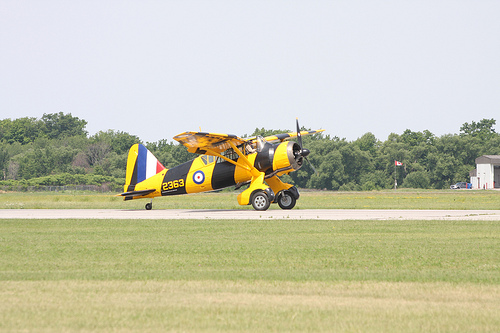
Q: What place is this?
A: It is an airport.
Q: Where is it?
A: This is at the airport.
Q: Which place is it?
A: It is an airport.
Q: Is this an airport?
A: Yes, it is an airport.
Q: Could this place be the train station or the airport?
A: It is the airport.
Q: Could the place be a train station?
A: No, it is an airport.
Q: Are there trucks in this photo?
A: No, there are no trucks.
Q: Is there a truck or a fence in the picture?
A: No, there are no trucks or fences.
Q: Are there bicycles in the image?
A: No, there are no bicycles.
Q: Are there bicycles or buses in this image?
A: No, there are no bicycles or buses.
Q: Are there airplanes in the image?
A: Yes, there is an airplane.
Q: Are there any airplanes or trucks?
A: Yes, there is an airplane.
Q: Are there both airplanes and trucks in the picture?
A: No, there is an airplane but no trucks.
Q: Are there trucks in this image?
A: No, there are no trucks.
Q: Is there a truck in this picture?
A: No, there are no trucks.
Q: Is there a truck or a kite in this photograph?
A: No, there are no trucks or kites.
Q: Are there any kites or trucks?
A: No, there are no trucks or kites.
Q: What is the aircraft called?
A: The aircraft is an airplane.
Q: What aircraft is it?
A: The aircraft is an airplane.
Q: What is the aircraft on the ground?
A: The aircraft is an airplane.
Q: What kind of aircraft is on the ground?
A: The aircraft is an airplane.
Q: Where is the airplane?
A: The airplane is on the ground.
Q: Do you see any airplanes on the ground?
A: Yes, there is an airplane on the ground.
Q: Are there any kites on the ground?
A: No, there is an airplane on the ground.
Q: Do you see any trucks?
A: No, there are no trucks.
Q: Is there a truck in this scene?
A: No, there are no trucks.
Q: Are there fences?
A: No, there are no fences.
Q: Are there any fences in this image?
A: No, there are no fences.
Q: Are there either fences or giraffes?
A: No, there are no fences or giraffes.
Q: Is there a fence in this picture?
A: No, there are no fences.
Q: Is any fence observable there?
A: No, there are no fences.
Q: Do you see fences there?
A: No, there are no fences.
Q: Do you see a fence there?
A: No, there are no fences.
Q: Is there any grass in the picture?
A: Yes, there is grass.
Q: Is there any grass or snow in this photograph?
A: Yes, there is grass.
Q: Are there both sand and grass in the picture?
A: No, there is grass but no sand.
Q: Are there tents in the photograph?
A: No, there are no tents.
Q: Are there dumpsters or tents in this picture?
A: No, there are no tents or dumpsters.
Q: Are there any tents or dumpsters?
A: No, there are no tents or dumpsters.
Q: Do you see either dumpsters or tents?
A: No, there are no tents or dumpsters.